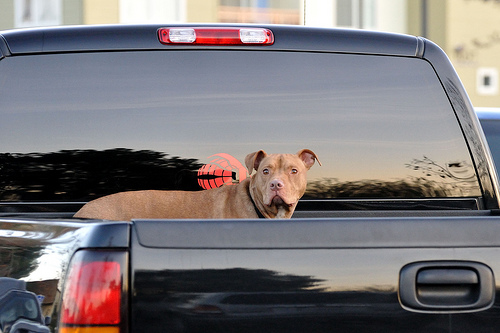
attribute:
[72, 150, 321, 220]
dog — brown, combed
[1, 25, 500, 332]
car — black, big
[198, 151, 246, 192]
sticker — red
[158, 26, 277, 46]
lights — red, white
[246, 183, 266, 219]
collar — black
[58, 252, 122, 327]
light — red, orange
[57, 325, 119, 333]
light — orange